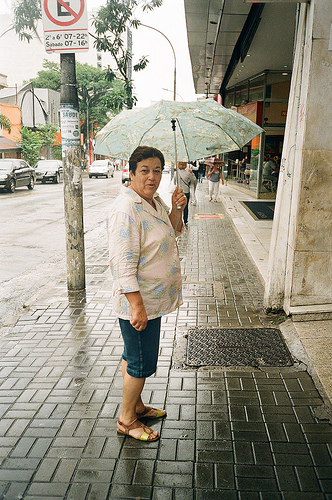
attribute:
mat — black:
[240, 198, 274, 220]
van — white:
[84, 155, 120, 183]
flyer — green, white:
[56, 99, 85, 149]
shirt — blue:
[207, 161, 223, 182]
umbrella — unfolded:
[85, 93, 268, 169]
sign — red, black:
[61, 100, 90, 149]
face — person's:
[121, 151, 175, 199]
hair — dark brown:
[128, 145, 165, 174]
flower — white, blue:
[137, 215, 155, 233]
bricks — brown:
[9, 304, 112, 447]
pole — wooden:
[39, 56, 92, 289]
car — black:
[0, 155, 38, 196]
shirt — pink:
[106, 199, 183, 288]